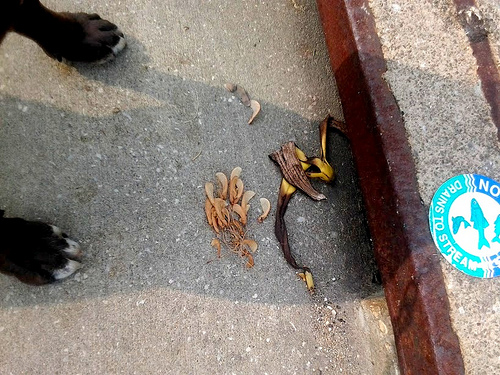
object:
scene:
[0, 0, 500, 375]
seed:
[248, 100, 260, 125]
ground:
[0, 0, 400, 375]